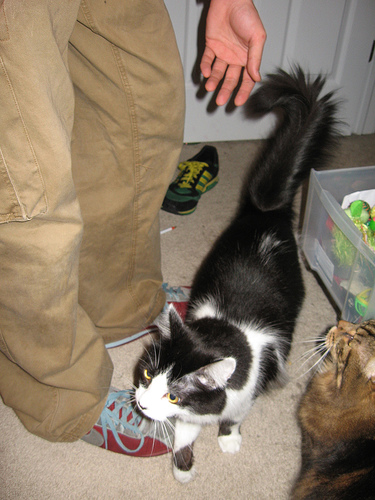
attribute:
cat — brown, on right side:
[307, 308, 373, 488]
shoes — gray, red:
[65, 368, 220, 471]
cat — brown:
[127, 164, 339, 429]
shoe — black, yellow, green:
[159, 144, 219, 215]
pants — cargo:
[2, 6, 191, 424]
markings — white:
[123, 360, 193, 431]